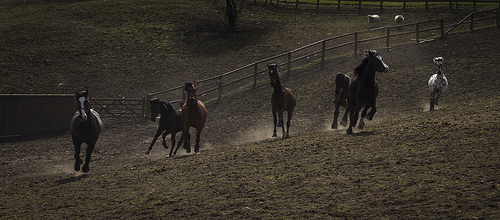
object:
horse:
[69, 91, 107, 174]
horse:
[178, 79, 208, 153]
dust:
[55, 159, 86, 176]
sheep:
[394, 14, 406, 25]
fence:
[0, 0, 500, 132]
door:
[92, 95, 144, 119]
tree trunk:
[222, 1, 237, 28]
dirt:
[30, 163, 65, 178]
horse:
[267, 63, 300, 138]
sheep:
[367, 14, 383, 24]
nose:
[77, 111, 90, 121]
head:
[186, 82, 198, 107]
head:
[74, 90, 96, 121]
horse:
[426, 56, 448, 111]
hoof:
[195, 148, 199, 154]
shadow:
[192, 21, 266, 56]